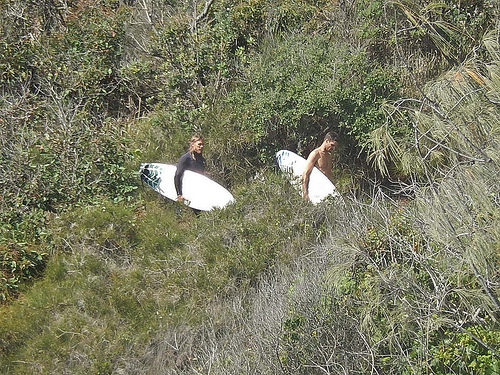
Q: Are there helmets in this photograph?
A: No, there are no helmets.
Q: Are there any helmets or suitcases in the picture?
A: No, there are no helmets or suitcases.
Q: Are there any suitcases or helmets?
A: No, there are no helmets or suitcases.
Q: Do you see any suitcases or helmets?
A: No, there are no helmets or suitcases.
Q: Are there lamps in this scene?
A: No, there are no lamps.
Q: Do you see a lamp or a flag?
A: No, there are no lamps or flags.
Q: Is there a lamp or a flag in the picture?
A: No, there are no lamps or flags.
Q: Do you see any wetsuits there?
A: Yes, there is a wetsuit.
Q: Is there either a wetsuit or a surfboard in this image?
A: Yes, there is a wetsuit.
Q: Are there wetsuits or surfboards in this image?
A: Yes, there is a wetsuit.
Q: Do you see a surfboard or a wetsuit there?
A: Yes, there is a wetsuit.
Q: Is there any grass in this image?
A: Yes, there is grass.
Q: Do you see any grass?
A: Yes, there is grass.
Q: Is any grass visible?
A: Yes, there is grass.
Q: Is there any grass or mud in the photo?
A: Yes, there is grass.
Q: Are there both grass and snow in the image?
A: No, there is grass but no snow.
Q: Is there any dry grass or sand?
A: Yes, there is dry grass.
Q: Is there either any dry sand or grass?
A: Yes, there is dry grass.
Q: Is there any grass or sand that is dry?
A: Yes, the grass is dry.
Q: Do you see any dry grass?
A: Yes, there is dry grass.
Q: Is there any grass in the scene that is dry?
A: Yes, there is grass that is dry.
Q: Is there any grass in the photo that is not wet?
A: Yes, there is dry grass.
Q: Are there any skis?
A: No, there are no skis.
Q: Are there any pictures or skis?
A: No, there are no skis or pictures.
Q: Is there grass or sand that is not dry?
A: No, there is grass but it is dry.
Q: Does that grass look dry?
A: Yes, the grass is dry.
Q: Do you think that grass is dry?
A: Yes, the grass is dry.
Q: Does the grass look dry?
A: Yes, the grass is dry.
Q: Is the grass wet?
A: No, the grass is dry.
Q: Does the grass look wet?
A: No, the grass is dry.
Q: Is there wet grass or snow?
A: No, there is grass but it is dry.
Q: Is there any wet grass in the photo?
A: No, there is grass but it is dry.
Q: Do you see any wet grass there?
A: No, there is grass but it is dry.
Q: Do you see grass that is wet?
A: No, there is grass but it is dry.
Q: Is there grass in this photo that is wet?
A: No, there is grass but it is dry.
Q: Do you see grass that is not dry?
A: No, there is grass but it is dry.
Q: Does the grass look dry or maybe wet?
A: The grass is dry.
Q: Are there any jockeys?
A: No, there are no jockeys.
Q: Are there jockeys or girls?
A: No, there are no jockeys or girls.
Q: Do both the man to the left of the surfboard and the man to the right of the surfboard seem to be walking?
A: Yes, both the man and the man are walking.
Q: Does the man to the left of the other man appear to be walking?
A: Yes, the man is walking.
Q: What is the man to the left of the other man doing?
A: The man is walking.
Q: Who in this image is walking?
A: The man is walking.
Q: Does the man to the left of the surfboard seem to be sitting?
A: No, the man is walking.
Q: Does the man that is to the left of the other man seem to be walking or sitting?
A: The man is walking.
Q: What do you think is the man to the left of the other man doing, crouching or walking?
A: The man is walking.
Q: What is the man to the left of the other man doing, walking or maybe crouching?
A: The man is walking.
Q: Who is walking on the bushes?
A: The man is walking on the bushes.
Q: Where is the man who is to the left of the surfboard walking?
A: The man is walking on the bushes.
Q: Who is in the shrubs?
A: The man is in the shrubs.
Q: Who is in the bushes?
A: The man is in the shrubs.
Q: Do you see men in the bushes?
A: Yes, there is a man in the bushes.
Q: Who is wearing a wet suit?
A: The man is wearing a wet suit.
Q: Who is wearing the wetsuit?
A: The man is wearing a wet suit.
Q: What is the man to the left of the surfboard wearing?
A: The man is wearing a wetsuit.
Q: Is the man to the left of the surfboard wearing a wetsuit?
A: Yes, the man is wearing a wetsuit.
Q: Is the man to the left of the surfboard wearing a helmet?
A: No, the man is wearing a wetsuit.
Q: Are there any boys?
A: No, there are no boys.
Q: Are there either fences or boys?
A: No, there are no boys or fences.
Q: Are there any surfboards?
A: Yes, there is a surfboard.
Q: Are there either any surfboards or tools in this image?
A: Yes, there is a surfboard.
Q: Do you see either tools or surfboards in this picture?
A: Yes, there is a surfboard.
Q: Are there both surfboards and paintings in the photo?
A: No, there is a surfboard but no paintings.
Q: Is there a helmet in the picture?
A: No, there are no helmets.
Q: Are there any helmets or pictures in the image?
A: No, there are no helmets or pictures.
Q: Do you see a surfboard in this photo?
A: Yes, there is a surfboard.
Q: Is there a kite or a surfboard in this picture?
A: Yes, there is a surfboard.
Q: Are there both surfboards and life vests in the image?
A: No, there is a surfboard but no life jackets.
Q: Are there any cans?
A: No, there are no cans.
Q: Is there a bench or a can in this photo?
A: No, there are no cans or benches.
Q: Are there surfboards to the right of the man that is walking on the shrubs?
A: Yes, there is a surfboard to the right of the man.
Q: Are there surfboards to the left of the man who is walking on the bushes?
A: No, the surfboard is to the right of the man.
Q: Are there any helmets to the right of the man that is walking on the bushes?
A: No, there is a surfboard to the right of the man.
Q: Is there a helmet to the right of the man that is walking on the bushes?
A: No, there is a surfboard to the right of the man.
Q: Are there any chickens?
A: No, there are no chickens.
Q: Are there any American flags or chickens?
A: No, there are no chickens or American flags.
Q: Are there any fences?
A: No, there are no fences.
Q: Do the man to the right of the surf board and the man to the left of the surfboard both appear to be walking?
A: Yes, both the man and the man are walking.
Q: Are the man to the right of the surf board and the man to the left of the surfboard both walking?
A: Yes, both the man and the man are walking.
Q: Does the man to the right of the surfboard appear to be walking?
A: Yes, the man is walking.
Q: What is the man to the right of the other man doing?
A: The man is walking.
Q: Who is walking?
A: The man is walking.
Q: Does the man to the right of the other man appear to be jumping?
A: No, the man is walking.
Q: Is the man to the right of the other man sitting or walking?
A: The man is walking.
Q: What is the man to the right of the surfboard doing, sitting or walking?
A: The man is walking.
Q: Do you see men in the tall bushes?
A: Yes, there is a man in the bushes.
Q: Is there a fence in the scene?
A: No, there are no fences.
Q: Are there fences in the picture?
A: No, there are no fences.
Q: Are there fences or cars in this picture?
A: No, there are no fences or cars.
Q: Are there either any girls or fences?
A: No, there are no fences or girls.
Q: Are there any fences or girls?
A: No, there are no fences or girls.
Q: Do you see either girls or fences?
A: No, there are no fences or girls.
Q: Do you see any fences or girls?
A: No, there are no fences or girls.